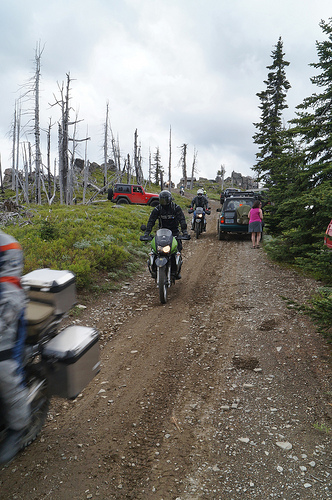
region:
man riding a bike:
[137, 185, 179, 287]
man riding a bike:
[189, 186, 207, 246]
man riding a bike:
[179, 185, 223, 261]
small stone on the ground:
[234, 428, 267, 471]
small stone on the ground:
[260, 414, 292, 483]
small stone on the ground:
[220, 460, 282, 494]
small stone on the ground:
[232, 400, 275, 460]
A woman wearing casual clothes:
[247, 200, 264, 248]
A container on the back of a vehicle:
[18, 267, 73, 315]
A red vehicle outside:
[108, 182, 162, 205]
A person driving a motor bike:
[187, 188, 209, 236]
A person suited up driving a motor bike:
[139, 189, 190, 301]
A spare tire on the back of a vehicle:
[233, 204, 251, 225]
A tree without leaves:
[15, 39, 45, 202]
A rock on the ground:
[275, 440, 291, 449]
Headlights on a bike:
[157, 244, 169, 252]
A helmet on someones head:
[158, 189, 170, 205]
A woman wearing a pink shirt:
[245, 198, 268, 248]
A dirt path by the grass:
[19, 228, 301, 498]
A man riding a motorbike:
[138, 190, 189, 300]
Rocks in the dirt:
[212, 322, 320, 496]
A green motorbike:
[139, 233, 189, 299]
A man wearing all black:
[145, 189, 187, 244]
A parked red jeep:
[105, 180, 160, 205]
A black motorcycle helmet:
[156, 189, 175, 210]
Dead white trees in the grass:
[2, 55, 169, 203]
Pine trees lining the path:
[253, 26, 330, 269]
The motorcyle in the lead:
[1, 268, 107, 460]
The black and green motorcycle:
[137, 220, 190, 304]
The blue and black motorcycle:
[187, 200, 212, 237]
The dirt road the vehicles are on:
[3, 200, 330, 499]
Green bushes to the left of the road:
[0, 159, 193, 326]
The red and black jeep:
[108, 179, 164, 208]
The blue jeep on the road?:
[214, 193, 263, 238]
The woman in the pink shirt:
[245, 196, 265, 246]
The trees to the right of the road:
[250, 15, 330, 348]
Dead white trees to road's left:
[1, 35, 175, 207]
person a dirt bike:
[134, 188, 200, 305]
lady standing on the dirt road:
[242, 200, 268, 252]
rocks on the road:
[218, 373, 327, 494]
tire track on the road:
[115, 350, 191, 499]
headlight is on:
[157, 242, 175, 256]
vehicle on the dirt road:
[211, 192, 268, 248]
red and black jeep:
[104, 177, 165, 208]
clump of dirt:
[233, 353, 260, 371]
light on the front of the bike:
[197, 211, 203, 219]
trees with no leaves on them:
[7, 49, 146, 210]